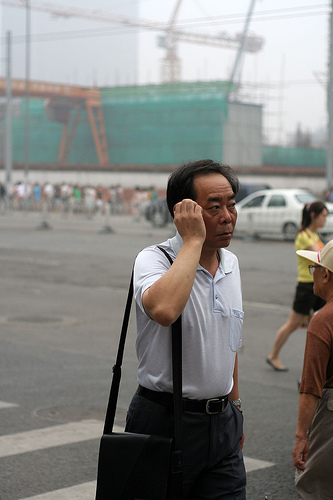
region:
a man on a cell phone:
[122, 156, 249, 323]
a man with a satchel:
[84, 151, 254, 498]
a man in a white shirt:
[79, 157, 254, 498]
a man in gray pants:
[87, 155, 264, 498]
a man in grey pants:
[89, 153, 257, 498]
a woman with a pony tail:
[264, 200, 331, 375]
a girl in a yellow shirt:
[262, 199, 330, 375]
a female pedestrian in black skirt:
[259, 200, 331, 373]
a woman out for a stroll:
[264, 200, 331, 371]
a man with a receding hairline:
[91, 156, 266, 498]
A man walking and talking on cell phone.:
[89, 155, 283, 491]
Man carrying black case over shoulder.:
[92, 244, 187, 496]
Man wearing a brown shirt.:
[293, 294, 330, 410]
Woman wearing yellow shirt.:
[284, 223, 328, 280]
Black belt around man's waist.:
[138, 378, 240, 417]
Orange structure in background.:
[2, 76, 129, 173]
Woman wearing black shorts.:
[290, 281, 327, 317]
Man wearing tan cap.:
[294, 240, 332, 276]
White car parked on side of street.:
[238, 184, 332, 240]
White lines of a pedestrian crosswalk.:
[4, 397, 97, 499]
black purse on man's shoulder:
[95, 249, 192, 497]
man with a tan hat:
[289, 237, 332, 484]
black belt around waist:
[127, 364, 255, 422]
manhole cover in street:
[5, 299, 80, 336]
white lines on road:
[1, 398, 285, 497]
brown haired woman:
[270, 197, 327, 381]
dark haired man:
[99, 152, 267, 492]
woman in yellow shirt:
[285, 199, 331, 364]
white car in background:
[229, 176, 331, 240]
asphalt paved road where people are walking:
[4, 225, 328, 402]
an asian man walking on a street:
[79, 141, 284, 493]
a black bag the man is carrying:
[84, 354, 185, 498]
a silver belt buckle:
[204, 395, 229, 417]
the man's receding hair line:
[170, 160, 236, 191]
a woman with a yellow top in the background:
[262, 199, 329, 379]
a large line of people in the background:
[13, 174, 154, 217]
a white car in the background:
[234, 189, 330, 238]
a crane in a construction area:
[36, 6, 293, 101]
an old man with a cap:
[283, 240, 331, 302]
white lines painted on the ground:
[4, 404, 99, 498]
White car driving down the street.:
[243, 182, 330, 239]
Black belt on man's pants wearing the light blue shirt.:
[140, 394, 236, 412]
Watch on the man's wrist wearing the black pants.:
[231, 395, 244, 412]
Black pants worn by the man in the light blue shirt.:
[139, 387, 246, 499]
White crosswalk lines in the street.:
[2, 399, 190, 498]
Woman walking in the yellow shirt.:
[290, 195, 327, 369]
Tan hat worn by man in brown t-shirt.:
[294, 242, 331, 268]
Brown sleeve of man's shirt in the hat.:
[298, 310, 331, 393]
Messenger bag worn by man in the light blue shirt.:
[95, 426, 188, 498]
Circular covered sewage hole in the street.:
[3, 309, 81, 333]